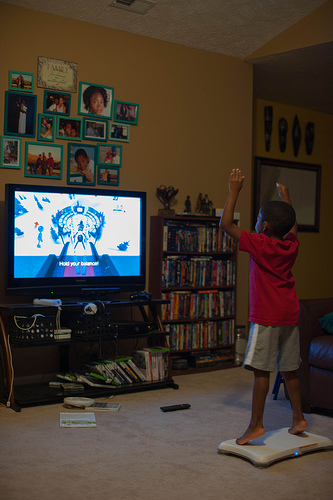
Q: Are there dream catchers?
A: No, there are no dream catchers.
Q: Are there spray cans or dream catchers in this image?
A: No, there are no dream catchers or spray cans.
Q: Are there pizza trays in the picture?
A: No, there are no pizza trays.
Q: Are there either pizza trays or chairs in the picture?
A: No, there are no pizza trays or chairs.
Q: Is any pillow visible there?
A: No, there are no pillows.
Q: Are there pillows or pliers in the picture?
A: No, there are no pillows or pliers.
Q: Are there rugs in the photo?
A: No, there are no rugs.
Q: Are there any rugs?
A: No, there are no rugs.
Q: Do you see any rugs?
A: No, there are no rugs.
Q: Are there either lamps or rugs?
A: No, there are no rugs or lamps.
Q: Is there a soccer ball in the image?
A: No, there are no soccer balls.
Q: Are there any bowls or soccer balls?
A: No, there are no soccer balls or bowls.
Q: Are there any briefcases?
A: No, there are no briefcases.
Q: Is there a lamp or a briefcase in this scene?
A: No, there are no briefcases or lamps.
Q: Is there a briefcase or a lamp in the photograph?
A: No, there are no briefcases or lamps.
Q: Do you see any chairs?
A: No, there are no chairs.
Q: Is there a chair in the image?
A: No, there are no chairs.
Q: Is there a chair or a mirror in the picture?
A: No, there are no chairs or mirrors.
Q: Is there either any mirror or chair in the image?
A: No, there are no chairs or mirrors.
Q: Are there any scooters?
A: No, there are no scooters.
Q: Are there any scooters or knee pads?
A: No, there are no scooters or knee pads.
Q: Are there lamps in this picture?
A: No, there are no lamps.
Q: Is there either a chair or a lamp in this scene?
A: No, there are no lamps or chairs.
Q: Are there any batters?
A: No, there are no batters.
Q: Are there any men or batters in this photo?
A: No, there are no batters or men.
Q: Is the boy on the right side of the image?
A: Yes, the boy is on the right of the image.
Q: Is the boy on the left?
A: No, the boy is on the right of the image.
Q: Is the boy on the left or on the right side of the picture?
A: The boy is on the right of the image.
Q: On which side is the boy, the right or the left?
A: The boy is on the right of the image.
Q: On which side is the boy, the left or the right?
A: The boy is on the right of the image.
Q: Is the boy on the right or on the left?
A: The boy is on the right of the image.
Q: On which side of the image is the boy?
A: The boy is on the right of the image.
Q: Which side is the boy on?
A: The boy is on the right of the image.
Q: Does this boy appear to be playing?
A: Yes, the boy is playing.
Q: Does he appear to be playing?
A: Yes, the boy is playing.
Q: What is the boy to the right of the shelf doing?
A: The boy is playing.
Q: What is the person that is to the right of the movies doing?
A: The boy is playing.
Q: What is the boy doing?
A: The boy is playing.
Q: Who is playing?
A: The boy is playing.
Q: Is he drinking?
A: No, the boy is playing.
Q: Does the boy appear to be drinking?
A: No, the boy is playing.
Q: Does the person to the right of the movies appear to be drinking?
A: No, the boy is playing.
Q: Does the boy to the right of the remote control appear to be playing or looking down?
A: The boy is playing.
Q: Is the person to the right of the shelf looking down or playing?
A: The boy is playing.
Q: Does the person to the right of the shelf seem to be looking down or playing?
A: The boy is playing.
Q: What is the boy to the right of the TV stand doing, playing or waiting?
A: The boy is playing.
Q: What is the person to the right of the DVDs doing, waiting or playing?
A: The boy is playing.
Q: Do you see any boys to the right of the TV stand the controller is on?
A: Yes, there is a boy to the right of the TV stand.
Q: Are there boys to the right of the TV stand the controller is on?
A: Yes, there is a boy to the right of the TV stand.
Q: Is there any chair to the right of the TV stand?
A: No, there is a boy to the right of the TV stand.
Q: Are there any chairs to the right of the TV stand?
A: No, there is a boy to the right of the TV stand.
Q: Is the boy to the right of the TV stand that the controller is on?
A: Yes, the boy is to the right of the TV stand.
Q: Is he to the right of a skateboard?
A: No, the boy is to the right of the TV stand.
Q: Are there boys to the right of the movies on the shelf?
A: Yes, there is a boy to the right of the movies.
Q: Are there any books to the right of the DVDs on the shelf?
A: No, there is a boy to the right of the movies.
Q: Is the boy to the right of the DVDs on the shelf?
A: Yes, the boy is to the right of the movies.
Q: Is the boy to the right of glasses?
A: No, the boy is to the right of the movies.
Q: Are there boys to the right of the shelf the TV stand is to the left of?
A: Yes, there is a boy to the right of the shelf.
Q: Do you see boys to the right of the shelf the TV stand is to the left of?
A: Yes, there is a boy to the right of the shelf.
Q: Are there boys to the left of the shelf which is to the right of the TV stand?
A: No, the boy is to the right of the shelf.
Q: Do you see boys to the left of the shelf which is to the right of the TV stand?
A: No, the boy is to the right of the shelf.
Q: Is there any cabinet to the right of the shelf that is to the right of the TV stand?
A: No, there is a boy to the right of the shelf.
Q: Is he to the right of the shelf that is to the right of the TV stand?
A: Yes, the boy is to the right of the shelf.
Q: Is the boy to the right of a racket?
A: No, the boy is to the right of the shelf.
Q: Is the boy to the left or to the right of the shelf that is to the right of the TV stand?
A: The boy is to the right of the shelf.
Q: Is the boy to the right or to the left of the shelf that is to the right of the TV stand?
A: The boy is to the right of the shelf.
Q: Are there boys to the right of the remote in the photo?
A: Yes, there is a boy to the right of the remote.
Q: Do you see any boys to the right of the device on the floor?
A: Yes, there is a boy to the right of the remote.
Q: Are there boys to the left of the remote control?
A: No, the boy is to the right of the remote control.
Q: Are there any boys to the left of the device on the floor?
A: No, the boy is to the right of the remote control.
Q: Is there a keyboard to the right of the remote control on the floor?
A: No, there is a boy to the right of the remote control.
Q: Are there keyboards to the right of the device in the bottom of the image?
A: No, there is a boy to the right of the remote control.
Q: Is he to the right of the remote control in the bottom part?
A: Yes, the boy is to the right of the remote control.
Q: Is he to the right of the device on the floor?
A: Yes, the boy is to the right of the remote control.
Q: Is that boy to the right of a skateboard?
A: No, the boy is to the right of the remote control.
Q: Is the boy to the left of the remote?
A: No, the boy is to the right of the remote.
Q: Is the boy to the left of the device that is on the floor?
A: No, the boy is to the right of the remote.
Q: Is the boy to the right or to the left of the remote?
A: The boy is to the right of the remote.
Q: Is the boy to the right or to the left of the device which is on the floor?
A: The boy is to the right of the remote.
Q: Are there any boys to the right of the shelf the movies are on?
A: Yes, there is a boy to the right of the shelf.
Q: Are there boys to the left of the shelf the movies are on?
A: No, the boy is to the right of the shelf.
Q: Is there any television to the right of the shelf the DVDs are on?
A: No, there is a boy to the right of the shelf.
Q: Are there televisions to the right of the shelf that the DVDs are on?
A: No, there is a boy to the right of the shelf.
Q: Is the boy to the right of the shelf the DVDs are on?
A: Yes, the boy is to the right of the shelf.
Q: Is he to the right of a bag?
A: No, the boy is to the right of the shelf.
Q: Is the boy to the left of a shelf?
A: No, the boy is to the right of a shelf.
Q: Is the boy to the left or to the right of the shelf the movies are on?
A: The boy is to the right of the shelf.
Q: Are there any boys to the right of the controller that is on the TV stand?
A: Yes, there is a boy to the right of the controller.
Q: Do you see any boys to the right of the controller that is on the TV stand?
A: Yes, there is a boy to the right of the controller.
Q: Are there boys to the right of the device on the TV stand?
A: Yes, there is a boy to the right of the controller.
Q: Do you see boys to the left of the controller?
A: No, the boy is to the right of the controller.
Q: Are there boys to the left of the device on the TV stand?
A: No, the boy is to the right of the controller.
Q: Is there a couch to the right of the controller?
A: No, there is a boy to the right of the controller.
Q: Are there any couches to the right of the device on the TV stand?
A: No, there is a boy to the right of the controller.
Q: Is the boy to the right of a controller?
A: Yes, the boy is to the right of a controller.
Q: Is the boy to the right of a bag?
A: No, the boy is to the right of a controller.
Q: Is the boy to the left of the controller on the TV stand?
A: No, the boy is to the right of the controller.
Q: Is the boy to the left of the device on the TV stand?
A: No, the boy is to the right of the controller.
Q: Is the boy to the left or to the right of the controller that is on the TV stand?
A: The boy is to the right of the controller.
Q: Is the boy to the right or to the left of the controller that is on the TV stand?
A: The boy is to the right of the controller.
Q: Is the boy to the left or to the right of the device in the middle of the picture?
A: The boy is to the right of the controller.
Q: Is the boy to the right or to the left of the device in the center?
A: The boy is to the right of the controller.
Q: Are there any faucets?
A: No, there are no faucets.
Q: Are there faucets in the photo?
A: No, there are no faucets.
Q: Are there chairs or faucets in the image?
A: No, there are no faucets or chairs.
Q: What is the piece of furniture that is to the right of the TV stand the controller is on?
A: The piece of furniture is a shelf.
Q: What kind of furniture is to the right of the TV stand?
A: The piece of furniture is a shelf.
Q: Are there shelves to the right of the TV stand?
A: Yes, there is a shelf to the right of the TV stand.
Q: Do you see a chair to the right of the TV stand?
A: No, there is a shelf to the right of the TV stand.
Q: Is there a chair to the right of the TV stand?
A: No, there is a shelf to the right of the TV stand.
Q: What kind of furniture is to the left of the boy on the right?
A: The piece of furniture is a shelf.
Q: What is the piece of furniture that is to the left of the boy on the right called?
A: The piece of furniture is a shelf.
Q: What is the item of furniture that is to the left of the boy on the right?
A: The piece of furniture is a shelf.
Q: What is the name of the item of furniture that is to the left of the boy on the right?
A: The piece of furniture is a shelf.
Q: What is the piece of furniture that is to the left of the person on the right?
A: The piece of furniture is a shelf.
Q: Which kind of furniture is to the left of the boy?
A: The piece of furniture is a shelf.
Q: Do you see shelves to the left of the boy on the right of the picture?
A: Yes, there is a shelf to the left of the boy.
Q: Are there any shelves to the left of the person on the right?
A: Yes, there is a shelf to the left of the boy.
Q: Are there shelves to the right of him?
A: No, the shelf is to the left of the boy.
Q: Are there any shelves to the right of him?
A: No, the shelf is to the left of the boy.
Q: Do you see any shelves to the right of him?
A: No, the shelf is to the left of the boy.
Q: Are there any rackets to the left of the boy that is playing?
A: No, there is a shelf to the left of the boy.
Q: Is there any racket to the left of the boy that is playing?
A: No, there is a shelf to the left of the boy.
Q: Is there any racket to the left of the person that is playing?
A: No, there is a shelf to the left of the boy.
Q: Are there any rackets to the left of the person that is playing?
A: No, there is a shelf to the left of the boy.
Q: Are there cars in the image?
A: No, there are no cars.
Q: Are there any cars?
A: No, there are no cars.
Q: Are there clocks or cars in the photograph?
A: No, there are no cars or clocks.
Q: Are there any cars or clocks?
A: No, there are no cars or clocks.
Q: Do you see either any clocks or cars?
A: No, there are no cars or clocks.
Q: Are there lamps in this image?
A: No, there are no lamps.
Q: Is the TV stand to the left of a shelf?
A: Yes, the TV stand is to the left of a shelf.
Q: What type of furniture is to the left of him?
A: The piece of furniture is a TV stand.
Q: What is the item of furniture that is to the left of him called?
A: The piece of furniture is a TV stand.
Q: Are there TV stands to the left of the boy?
A: Yes, there is a TV stand to the left of the boy.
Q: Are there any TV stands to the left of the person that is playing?
A: Yes, there is a TV stand to the left of the boy.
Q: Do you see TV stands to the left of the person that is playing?
A: Yes, there is a TV stand to the left of the boy.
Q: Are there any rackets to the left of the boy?
A: No, there is a TV stand to the left of the boy.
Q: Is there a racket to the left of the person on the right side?
A: No, there is a TV stand to the left of the boy.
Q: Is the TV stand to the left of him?
A: Yes, the TV stand is to the left of a boy.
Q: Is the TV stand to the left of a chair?
A: No, the TV stand is to the left of a boy.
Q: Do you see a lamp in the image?
A: No, there are no lamps.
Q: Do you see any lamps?
A: No, there are no lamps.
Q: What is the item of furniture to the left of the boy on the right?
A: The piece of furniture is a shelf.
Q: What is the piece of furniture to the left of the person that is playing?
A: The piece of furniture is a shelf.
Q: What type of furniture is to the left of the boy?
A: The piece of furniture is a shelf.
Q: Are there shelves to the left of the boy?
A: Yes, there is a shelf to the left of the boy.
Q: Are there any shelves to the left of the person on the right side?
A: Yes, there is a shelf to the left of the boy.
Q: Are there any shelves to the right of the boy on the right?
A: No, the shelf is to the left of the boy.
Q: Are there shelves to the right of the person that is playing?
A: No, the shelf is to the left of the boy.